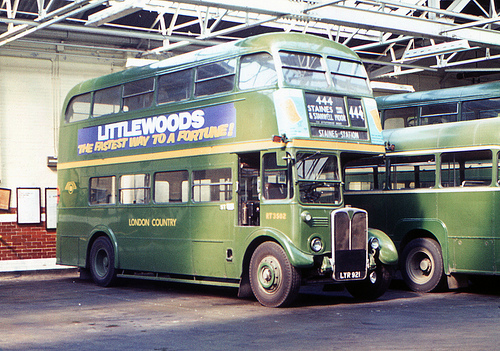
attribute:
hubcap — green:
[255, 252, 282, 295]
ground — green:
[418, 143, 455, 167]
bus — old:
[71, 52, 383, 311]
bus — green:
[338, 118, 499, 296]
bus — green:
[367, 71, 499, 136]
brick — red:
[16, 229, 56, 257]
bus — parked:
[337, 101, 499, 301]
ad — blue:
[73, 100, 239, 159]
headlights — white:
[304, 229, 383, 258]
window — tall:
[232, 149, 263, 226]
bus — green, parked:
[55, 29, 398, 311]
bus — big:
[47, 47, 403, 308]